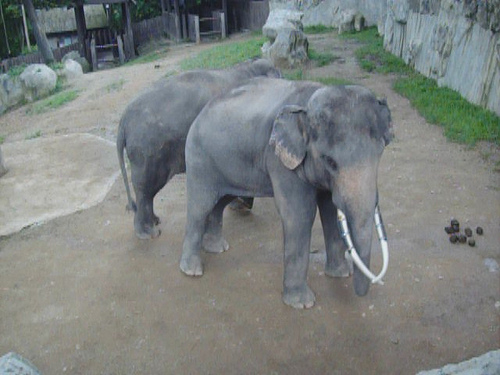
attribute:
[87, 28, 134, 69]
gate — brown, wooden, logs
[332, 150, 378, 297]
trunk — dirty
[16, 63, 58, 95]
grey boulder — large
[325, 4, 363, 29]
grey boulder — large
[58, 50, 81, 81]
grey boulder — large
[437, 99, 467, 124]
grass — green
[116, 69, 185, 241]
elephant — small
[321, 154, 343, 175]
eye — open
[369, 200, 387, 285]
tusk — long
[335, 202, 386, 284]
tusk — long, white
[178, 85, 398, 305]
elephant — large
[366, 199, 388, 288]
tusk — white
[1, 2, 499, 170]
grass — green